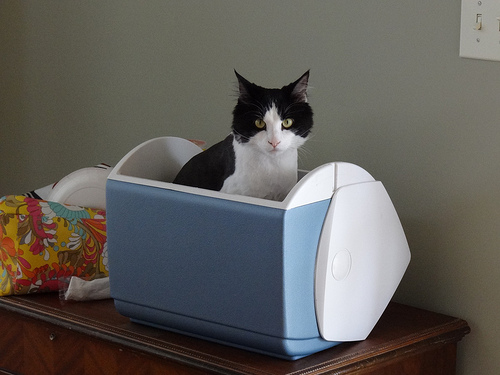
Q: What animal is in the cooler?
A: A cat.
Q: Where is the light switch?
A: On the wall.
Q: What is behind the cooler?
A: A patterned bag.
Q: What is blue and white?
A: The cooler.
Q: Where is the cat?
A: Inside the cooler.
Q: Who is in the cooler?
A: The cat.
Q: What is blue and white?
A: Cooler.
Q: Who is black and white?
A: Cat.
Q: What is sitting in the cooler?
A: Cat.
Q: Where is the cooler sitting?
A: On the table.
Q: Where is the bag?
A: Next to the cooler.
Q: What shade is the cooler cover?
A: White.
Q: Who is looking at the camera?
A: Cat.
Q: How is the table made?
A: Wood.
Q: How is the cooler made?
A: Plastic.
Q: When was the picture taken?
A: Daytime.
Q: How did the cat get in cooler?
A: Jumped in.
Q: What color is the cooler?
A: Blue and white.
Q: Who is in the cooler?
A: Cat.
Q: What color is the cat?
A: Black and white.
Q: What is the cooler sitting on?
A: Table.